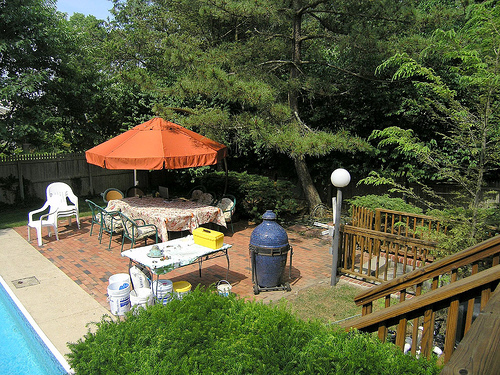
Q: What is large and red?
A: Umbrella.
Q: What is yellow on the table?
A: Toolbox.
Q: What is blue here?
A: The pool.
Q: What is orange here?
A: The umbrella.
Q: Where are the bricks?
A: On the patio.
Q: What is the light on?
A: A pole.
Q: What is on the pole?
A: A light.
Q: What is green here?
A: The trees?.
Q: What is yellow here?
A: A tool box.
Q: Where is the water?
A: In the pool.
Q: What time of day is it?
A: Afternoon.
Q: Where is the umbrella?
A: Over the table.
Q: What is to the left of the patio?
A: A pool.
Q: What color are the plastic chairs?
A: White.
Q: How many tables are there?
A: Two.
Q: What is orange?
A: The umbrella.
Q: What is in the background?
A: Trees.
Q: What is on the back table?
A: A tablecloth.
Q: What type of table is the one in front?
A: A folding table.